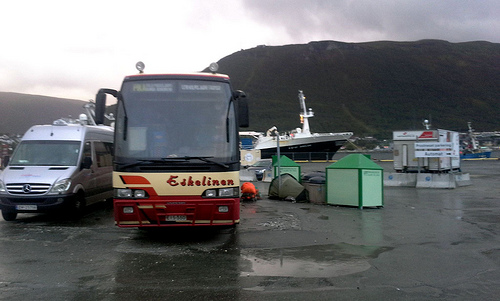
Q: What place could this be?
A: It is a parking lot.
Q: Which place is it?
A: It is a parking lot.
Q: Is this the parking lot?
A: Yes, it is the parking lot.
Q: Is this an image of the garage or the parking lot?
A: It is showing the parking lot.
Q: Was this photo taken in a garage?
A: No, the picture was taken in a parking lot.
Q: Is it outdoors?
A: Yes, it is outdoors.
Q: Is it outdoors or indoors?
A: It is outdoors.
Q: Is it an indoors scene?
A: No, it is outdoors.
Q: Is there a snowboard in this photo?
A: No, there are no snowboards.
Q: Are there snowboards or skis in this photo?
A: No, there are no snowboards or skis.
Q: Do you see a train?
A: No, there are no trains.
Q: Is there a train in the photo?
A: No, there are no trains.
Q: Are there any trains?
A: No, there are no trains.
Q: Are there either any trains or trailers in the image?
A: No, there are no trains or trailers.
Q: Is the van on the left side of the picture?
A: Yes, the van is on the left of the image.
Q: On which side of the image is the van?
A: The van is on the left of the image.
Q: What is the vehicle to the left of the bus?
A: The vehicle is a van.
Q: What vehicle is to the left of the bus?
A: The vehicle is a van.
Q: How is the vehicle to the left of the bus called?
A: The vehicle is a van.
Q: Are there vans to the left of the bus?
A: Yes, there is a van to the left of the bus.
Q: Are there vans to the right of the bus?
A: No, the van is to the left of the bus.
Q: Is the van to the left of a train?
A: No, the van is to the left of the bus.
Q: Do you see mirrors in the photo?
A: Yes, there is a mirror.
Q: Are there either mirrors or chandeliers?
A: Yes, there is a mirror.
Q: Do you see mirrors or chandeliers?
A: Yes, there is a mirror.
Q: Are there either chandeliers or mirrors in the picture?
A: Yes, there is a mirror.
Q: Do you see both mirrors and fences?
A: No, there is a mirror but no fences.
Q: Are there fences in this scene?
A: No, there are no fences.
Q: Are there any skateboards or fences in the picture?
A: No, there are no fences or skateboards.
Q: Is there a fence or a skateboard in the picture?
A: No, there are no fences or skateboards.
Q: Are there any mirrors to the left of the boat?
A: Yes, there is a mirror to the left of the boat.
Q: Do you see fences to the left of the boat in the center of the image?
A: No, there is a mirror to the left of the boat.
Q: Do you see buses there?
A: Yes, there is a bus.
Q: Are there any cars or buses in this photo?
A: Yes, there is a bus.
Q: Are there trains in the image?
A: No, there are no trains.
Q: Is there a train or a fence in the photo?
A: No, there are no trains or fences.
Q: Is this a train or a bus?
A: This is a bus.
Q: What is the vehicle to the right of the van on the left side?
A: The vehicle is a bus.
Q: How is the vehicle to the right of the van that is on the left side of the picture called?
A: The vehicle is a bus.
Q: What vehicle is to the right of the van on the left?
A: The vehicle is a bus.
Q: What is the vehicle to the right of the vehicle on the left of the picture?
A: The vehicle is a bus.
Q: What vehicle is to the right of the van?
A: The vehicle is a bus.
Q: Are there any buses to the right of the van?
A: Yes, there is a bus to the right of the van.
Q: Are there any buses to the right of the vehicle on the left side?
A: Yes, there is a bus to the right of the van.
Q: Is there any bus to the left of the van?
A: No, the bus is to the right of the van.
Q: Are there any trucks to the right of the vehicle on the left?
A: No, there is a bus to the right of the van.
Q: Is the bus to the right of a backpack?
A: No, the bus is to the right of the van.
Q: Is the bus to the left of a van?
A: No, the bus is to the right of a van.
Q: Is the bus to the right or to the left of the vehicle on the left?
A: The bus is to the right of the van.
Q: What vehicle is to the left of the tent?
A: The vehicle is a bus.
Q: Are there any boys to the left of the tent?
A: No, there is a bus to the left of the tent.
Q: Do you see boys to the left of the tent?
A: No, there is a bus to the left of the tent.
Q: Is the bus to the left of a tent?
A: Yes, the bus is to the left of a tent.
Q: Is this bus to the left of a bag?
A: No, the bus is to the left of a tent.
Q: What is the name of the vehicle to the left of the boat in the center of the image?
A: The vehicle is a bus.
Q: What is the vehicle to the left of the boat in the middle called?
A: The vehicle is a bus.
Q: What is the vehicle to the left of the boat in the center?
A: The vehicle is a bus.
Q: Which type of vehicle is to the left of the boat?
A: The vehicle is a bus.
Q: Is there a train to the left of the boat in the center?
A: No, there is a bus to the left of the boat.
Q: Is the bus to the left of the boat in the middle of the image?
A: Yes, the bus is to the left of the boat.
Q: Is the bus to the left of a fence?
A: No, the bus is to the left of the boat.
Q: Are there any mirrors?
A: Yes, there is a mirror.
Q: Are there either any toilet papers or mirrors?
A: Yes, there is a mirror.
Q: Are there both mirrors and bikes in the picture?
A: No, there is a mirror but no bikes.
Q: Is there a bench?
A: No, there are no benches.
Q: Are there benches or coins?
A: No, there are no benches or coins.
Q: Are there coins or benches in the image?
A: No, there are no benches or coins.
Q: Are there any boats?
A: Yes, there is a boat.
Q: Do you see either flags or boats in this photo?
A: Yes, there is a boat.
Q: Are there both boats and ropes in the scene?
A: No, there is a boat but no ropes.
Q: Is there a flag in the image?
A: No, there are no flags.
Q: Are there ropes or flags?
A: No, there are no flags or ropes.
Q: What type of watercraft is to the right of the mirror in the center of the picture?
A: The watercraft is a boat.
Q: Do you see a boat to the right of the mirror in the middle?
A: Yes, there is a boat to the right of the mirror.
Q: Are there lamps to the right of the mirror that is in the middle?
A: No, there is a boat to the right of the mirror.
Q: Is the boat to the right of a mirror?
A: Yes, the boat is to the right of a mirror.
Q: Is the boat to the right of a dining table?
A: No, the boat is to the right of a mirror.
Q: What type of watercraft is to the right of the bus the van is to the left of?
A: The watercraft is a boat.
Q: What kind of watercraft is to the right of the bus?
A: The watercraft is a boat.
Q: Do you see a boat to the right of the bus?
A: Yes, there is a boat to the right of the bus.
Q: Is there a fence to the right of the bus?
A: No, there is a boat to the right of the bus.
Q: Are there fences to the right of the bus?
A: No, there is a boat to the right of the bus.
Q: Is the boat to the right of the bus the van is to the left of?
A: Yes, the boat is to the right of the bus.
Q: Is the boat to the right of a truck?
A: No, the boat is to the right of the bus.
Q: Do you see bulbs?
A: No, there are no bulbs.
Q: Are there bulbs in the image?
A: No, there are no bulbs.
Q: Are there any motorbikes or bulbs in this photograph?
A: No, there are no bulbs or motorbikes.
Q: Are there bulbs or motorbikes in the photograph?
A: No, there are no bulbs or motorbikes.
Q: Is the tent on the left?
A: No, the tent is on the right of the image.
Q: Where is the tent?
A: The tent is on the parking lot.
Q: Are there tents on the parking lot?
A: Yes, there is a tent on the parking lot.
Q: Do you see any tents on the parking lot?
A: Yes, there is a tent on the parking lot.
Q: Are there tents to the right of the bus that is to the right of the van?
A: Yes, there is a tent to the right of the bus.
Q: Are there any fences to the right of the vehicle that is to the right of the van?
A: No, there is a tent to the right of the bus.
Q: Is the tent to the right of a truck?
A: No, the tent is to the right of the bus.